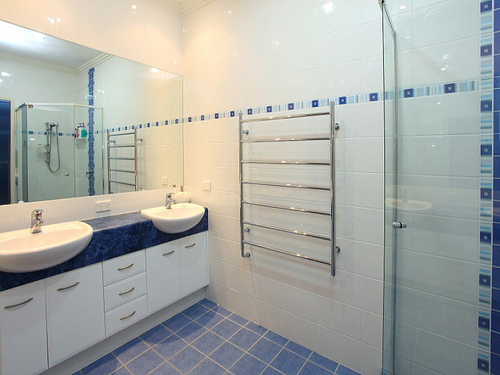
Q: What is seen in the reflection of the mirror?
A: Shower.